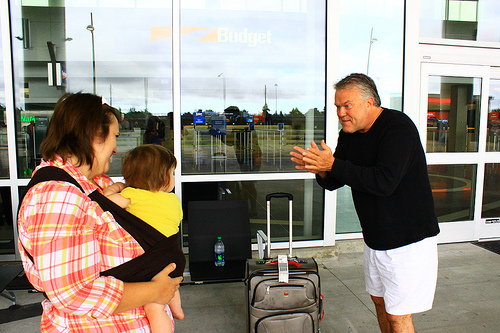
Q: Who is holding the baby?
A: A woman.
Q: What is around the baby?
A: Wrap around carrier.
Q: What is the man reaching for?
A: The baby.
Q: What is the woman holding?
A: A baby.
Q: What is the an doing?
A: Speaking to the baby.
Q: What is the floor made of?
A: Cement.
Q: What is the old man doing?
A: Clapping hands together.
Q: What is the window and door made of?
A: Glass.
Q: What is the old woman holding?
A: A baby.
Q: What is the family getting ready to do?
A: Travel together.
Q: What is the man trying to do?
A: Playing with baby.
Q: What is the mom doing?
A: Smiling at baby.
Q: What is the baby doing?
A: Observing man.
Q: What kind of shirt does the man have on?
A: A long sleeve shirt.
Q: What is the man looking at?
A: A baby.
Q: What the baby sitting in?
A: A sling.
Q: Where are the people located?
A: At an airport.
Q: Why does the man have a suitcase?
A: He is traveling.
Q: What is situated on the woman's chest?
A: A child.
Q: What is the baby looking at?
A: The man clapping.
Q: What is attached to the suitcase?
A: A tag.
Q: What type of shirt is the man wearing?
A: Long sleeves.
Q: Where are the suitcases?
A: On the sidewalk.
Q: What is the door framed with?
A: Metal.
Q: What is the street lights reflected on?
A: Window.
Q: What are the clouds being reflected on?
A: Window.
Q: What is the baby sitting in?
A: Carrier.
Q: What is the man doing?
A: Clapping.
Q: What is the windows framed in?
A: Metal.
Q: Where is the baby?
A: Attached to the woman.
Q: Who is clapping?
A: The man.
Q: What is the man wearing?
A: White shorts.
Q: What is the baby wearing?
A: Yellow shirt.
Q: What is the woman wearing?
A: Plaid shirt.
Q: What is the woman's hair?
A: Brown.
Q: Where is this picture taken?
A: At airport.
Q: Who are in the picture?
A: A man, woman and a baby.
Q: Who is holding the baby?
A: The woman.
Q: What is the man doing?
A: Asking the baby to come to him.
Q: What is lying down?
A: Luggage.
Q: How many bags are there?
A: Two.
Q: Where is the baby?
A: In the carrier.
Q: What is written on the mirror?
A: Budget.